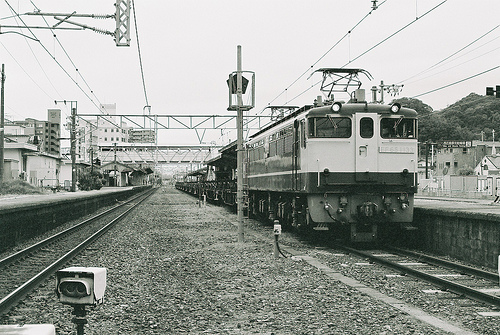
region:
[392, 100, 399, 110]
the left headlight of the train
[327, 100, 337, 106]
the right headlight of the train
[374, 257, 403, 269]
a section of the rail gauge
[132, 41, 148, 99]
part of an electricity wire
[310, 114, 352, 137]
the right front window of the train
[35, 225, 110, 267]
another section of a rail without a train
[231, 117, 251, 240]
a tall pole with a staircase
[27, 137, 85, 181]
houses beside the railway station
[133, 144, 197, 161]
section a metal bridge above the train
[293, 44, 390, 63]
section of electricity wires above the traon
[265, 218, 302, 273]
pole sticking from the ground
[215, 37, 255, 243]
long pole near train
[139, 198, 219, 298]
patch of gravel near the train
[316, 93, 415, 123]
lights on the train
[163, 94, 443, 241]
train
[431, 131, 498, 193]
houses behind the train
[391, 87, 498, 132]
trees behind the train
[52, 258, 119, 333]
device used to see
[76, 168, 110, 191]
small bushes near the train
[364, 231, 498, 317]
train tracks near the wall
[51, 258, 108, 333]
an old viewfinder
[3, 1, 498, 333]
a black and white photograph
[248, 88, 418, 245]
an old style locomotive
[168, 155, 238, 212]
empty cargo cars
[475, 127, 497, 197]
a church to the right of the train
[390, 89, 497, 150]
hills are in the distance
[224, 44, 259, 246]
an upright metal pole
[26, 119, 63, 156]
apartment buildings to the left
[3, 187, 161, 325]
long narrow train tracks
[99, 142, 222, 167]
a bridge over the train tracks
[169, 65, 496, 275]
Train is next to platform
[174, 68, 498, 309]
Train is on tracks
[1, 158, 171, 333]
Train is distant on left side tracks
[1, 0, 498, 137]
Wires above train provide electricity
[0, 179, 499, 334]
Platforms surround train tracks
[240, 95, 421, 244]
Engine has two headlights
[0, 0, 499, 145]
The sky is overcast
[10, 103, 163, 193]
Skyscrapers are in the background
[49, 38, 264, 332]
Train stoplights are next to tracks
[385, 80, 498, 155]
Trees are in the background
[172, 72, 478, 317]
Train car on tracks.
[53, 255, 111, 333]
Camera to capture movement.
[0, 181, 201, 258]
Train tracks and side walk.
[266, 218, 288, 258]
Electric outlet near train tracks.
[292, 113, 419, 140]
Windows in front of train.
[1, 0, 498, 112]
Cable lines for cable car.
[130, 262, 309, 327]
Patch of gray gravel.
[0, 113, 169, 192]
Buildings and side walk.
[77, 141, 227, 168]
Small bridge for pedestrians.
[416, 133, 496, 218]
House and building on road.